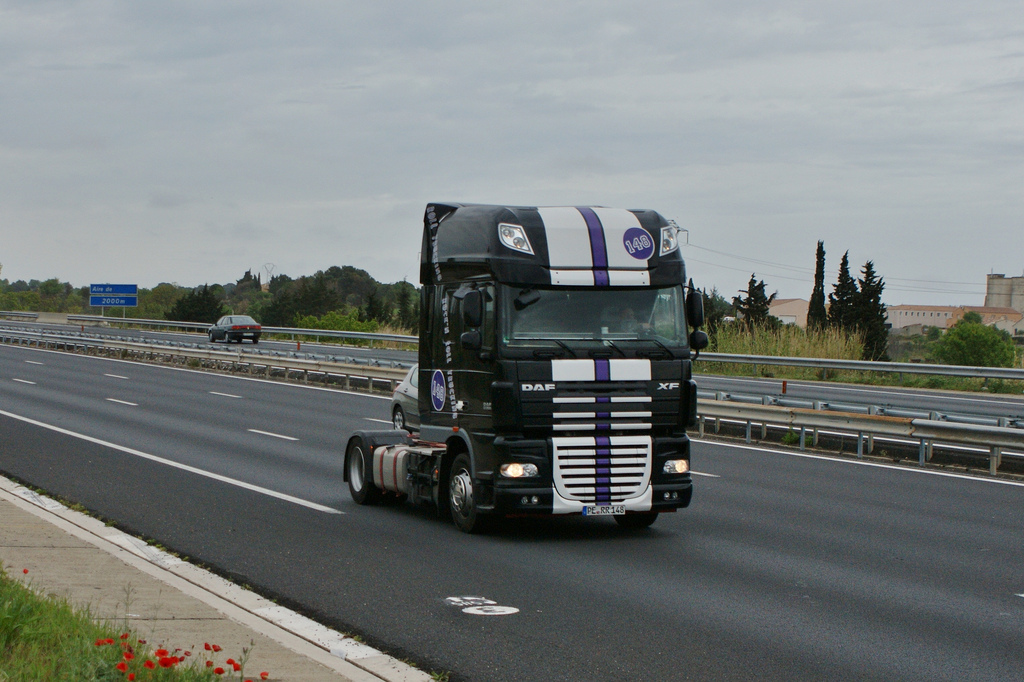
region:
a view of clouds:
[234, 60, 333, 155]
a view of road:
[569, 549, 684, 629]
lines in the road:
[138, 443, 345, 541]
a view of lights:
[477, 388, 563, 507]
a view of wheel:
[398, 391, 575, 608]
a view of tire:
[316, 413, 430, 535]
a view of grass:
[46, 563, 224, 680]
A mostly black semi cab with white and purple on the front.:
[342, 197, 693, 529]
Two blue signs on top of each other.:
[87, 280, 141, 312]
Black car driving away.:
[204, 314, 261, 344]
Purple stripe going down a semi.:
[572, 203, 611, 505]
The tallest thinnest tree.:
[806, 241, 826, 328]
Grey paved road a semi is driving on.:
[0, 340, 1022, 680]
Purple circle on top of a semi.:
[623, 228, 655, 264]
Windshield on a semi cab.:
[504, 280, 688, 347]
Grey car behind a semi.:
[392, 362, 424, 436]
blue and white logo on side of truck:
[400, 353, 470, 437]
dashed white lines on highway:
[6, 337, 446, 474]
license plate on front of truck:
[571, 494, 648, 529]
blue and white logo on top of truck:
[606, 219, 661, 267]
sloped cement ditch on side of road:
[6, 475, 437, 681]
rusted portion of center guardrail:
[782, 403, 934, 462]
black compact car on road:
[195, 309, 272, 354]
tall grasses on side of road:
[694, 324, 878, 388]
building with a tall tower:
[729, 267, 1020, 341]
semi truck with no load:
[319, 187, 703, 539]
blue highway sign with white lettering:
[62, 254, 155, 335]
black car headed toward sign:
[188, 307, 269, 356]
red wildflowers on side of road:
[0, 545, 273, 675]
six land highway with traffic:
[5, 297, 1020, 668]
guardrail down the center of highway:
[0, 305, 1021, 493]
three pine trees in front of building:
[785, 229, 904, 373]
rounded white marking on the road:
[438, 564, 531, 645]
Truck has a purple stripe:
[345, 198, 696, 528]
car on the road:
[0, 310, 1016, 674]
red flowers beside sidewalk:
[3, 468, 438, 680]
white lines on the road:
[5, 323, 1014, 677]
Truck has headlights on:
[345, 200, 696, 539]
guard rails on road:
[2, 315, 1012, 674]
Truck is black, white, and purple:
[337, 199, 693, 541]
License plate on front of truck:
[335, 200, 699, 537]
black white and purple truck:
[365, 179, 714, 549]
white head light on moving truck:
[495, 443, 541, 497]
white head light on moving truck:
[659, 448, 692, 481]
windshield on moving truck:
[497, 286, 685, 344]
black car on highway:
[191, 298, 261, 359]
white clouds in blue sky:
[249, 58, 392, 126]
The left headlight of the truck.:
[500, 457, 540, 478]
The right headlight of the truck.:
[662, 454, 689, 481]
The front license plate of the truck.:
[583, 495, 622, 516]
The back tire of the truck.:
[339, 451, 385, 490]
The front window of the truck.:
[510, 288, 684, 343]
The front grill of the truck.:
[561, 359, 650, 508]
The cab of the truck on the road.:
[413, 182, 702, 433]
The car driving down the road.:
[205, 309, 266, 349]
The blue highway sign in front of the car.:
[84, 284, 139, 308]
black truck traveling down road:
[346, 203, 698, 524]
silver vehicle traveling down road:
[390, 366, 422, 425]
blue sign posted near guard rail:
[88, 279, 139, 321]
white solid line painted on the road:
[0, 387, 343, 518]